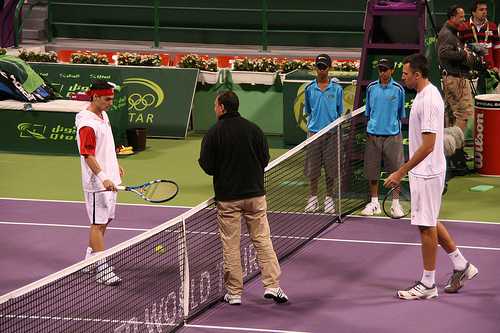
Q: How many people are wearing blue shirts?
A: Two.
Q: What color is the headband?
A: Red.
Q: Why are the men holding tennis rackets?
A: They're playing tennis.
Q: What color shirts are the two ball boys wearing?
A: Blue.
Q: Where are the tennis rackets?
A: In the player's hands.